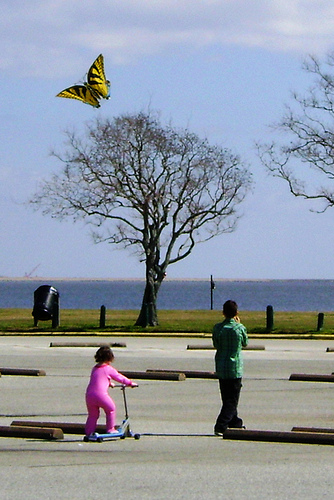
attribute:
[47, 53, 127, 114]
butterfly — black, yellow, flying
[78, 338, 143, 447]
girl — little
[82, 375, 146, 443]
scooter — blue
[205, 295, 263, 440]
boy — photographing, flying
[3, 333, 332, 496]
parking lot — gray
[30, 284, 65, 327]
can — metal, black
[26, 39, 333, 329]
trees — bare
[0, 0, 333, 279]
sky — blue, cloudy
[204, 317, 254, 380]
shirt — green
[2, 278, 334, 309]
water — blue, large, still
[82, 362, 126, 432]
jumper — pink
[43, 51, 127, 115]
kite — yellow, black